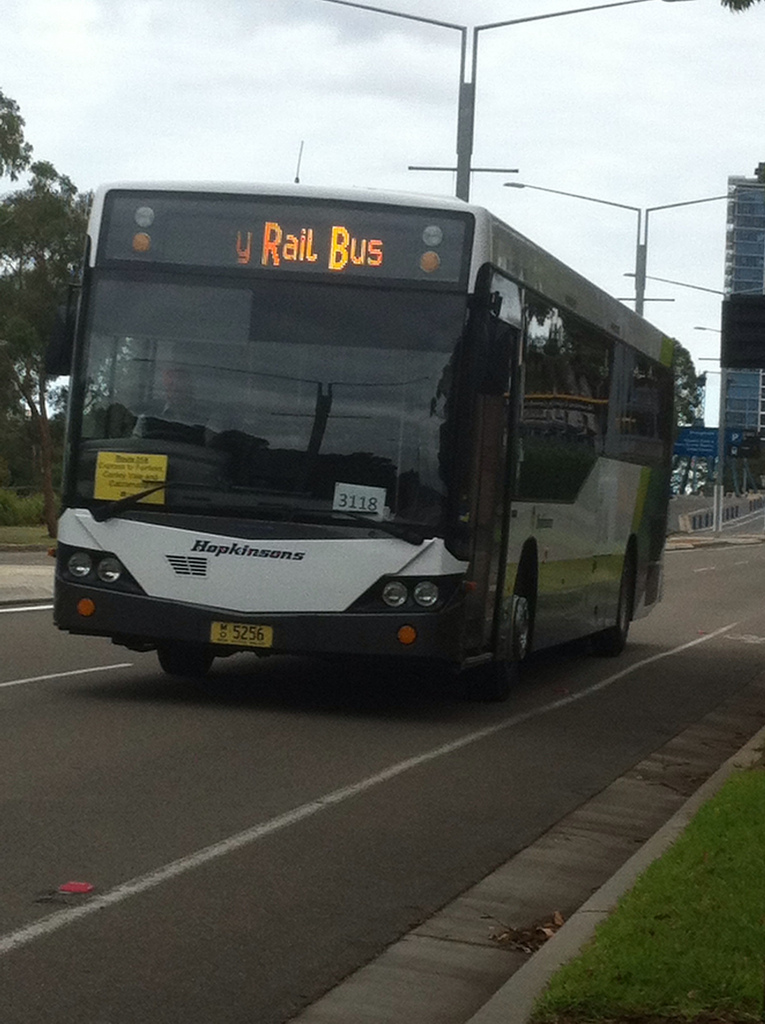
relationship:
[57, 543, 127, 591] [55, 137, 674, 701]
headlights on bus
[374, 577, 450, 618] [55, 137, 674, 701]
headlights on bus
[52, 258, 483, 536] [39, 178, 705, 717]
windshield on bus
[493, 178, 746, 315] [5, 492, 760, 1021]
light post on street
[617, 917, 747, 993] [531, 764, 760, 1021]
patch of grass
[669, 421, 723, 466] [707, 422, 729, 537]
sign on post